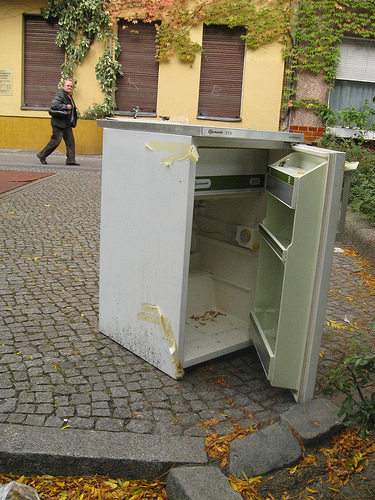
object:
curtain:
[327, 79, 374, 126]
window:
[326, 40, 375, 125]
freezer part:
[192, 168, 265, 192]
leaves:
[31, 477, 166, 497]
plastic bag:
[0, 481, 40, 500]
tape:
[137, 301, 184, 379]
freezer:
[95, 119, 359, 405]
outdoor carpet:
[0, 167, 54, 200]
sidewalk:
[0, 147, 98, 181]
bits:
[191, 309, 221, 326]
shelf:
[192, 265, 251, 293]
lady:
[36, 79, 81, 166]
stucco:
[0, 1, 288, 130]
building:
[0, 1, 375, 153]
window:
[198, 25, 243, 121]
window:
[113, 12, 159, 113]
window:
[19, 11, 70, 110]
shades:
[198, 23, 248, 118]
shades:
[114, 18, 156, 113]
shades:
[24, 14, 64, 108]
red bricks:
[287, 124, 325, 141]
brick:
[0, 312, 109, 398]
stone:
[45, 355, 173, 430]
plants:
[45, 0, 354, 97]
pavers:
[12, 289, 104, 382]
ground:
[1, 153, 373, 498]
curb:
[1, 399, 373, 498]